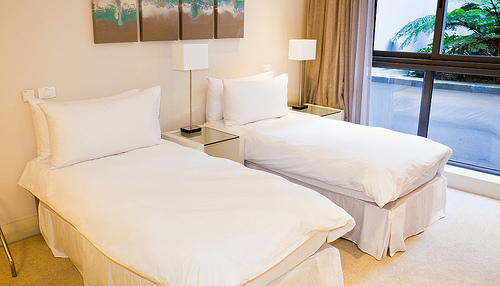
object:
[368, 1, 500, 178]
windows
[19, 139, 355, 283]
linen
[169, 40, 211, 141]
lamp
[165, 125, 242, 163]
night stand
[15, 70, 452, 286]
two beds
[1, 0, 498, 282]
hotel room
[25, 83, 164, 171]
pillows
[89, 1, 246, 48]
painting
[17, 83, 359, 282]
bed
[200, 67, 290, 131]
two pillows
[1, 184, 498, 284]
ground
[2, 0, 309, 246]
wall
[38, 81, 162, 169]
pillow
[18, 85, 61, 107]
lighting controls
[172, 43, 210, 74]
shade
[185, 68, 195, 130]
metal pole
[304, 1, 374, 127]
curtains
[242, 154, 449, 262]
bed skirt